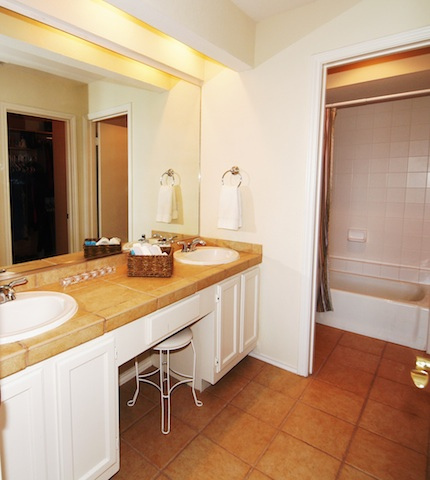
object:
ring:
[219, 163, 244, 191]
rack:
[221, 164, 242, 187]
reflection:
[343, 159, 428, 200]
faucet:
[175, 237, 206, 252]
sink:
[173, 245, 239, 266]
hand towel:
[215, 186, 243, 231]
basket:
[127, 242, 174, 277]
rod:
[324, 86, 429, 108]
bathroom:
[0, 2, 428, 478]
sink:
[0, 277, 82, 342]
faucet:
[0, 274, 30, 301]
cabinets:
[217, 271, 257, 384]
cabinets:
[61, 361, 120, 479]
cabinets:
[0, 369, 52, 477]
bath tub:
[315, 267, 429, 352]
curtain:
[315, 103, 337, 311]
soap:
[347, 229, 364, 241]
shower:
[314, 58, 428, 332]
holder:
[220, 162, 243, 187]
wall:
[201, 1, 428, 380]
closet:
[0, 108, 79, 266]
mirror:
[1, 8, 201, 281]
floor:
[112, 320, 428, 479]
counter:
[0, 236, 262, 376]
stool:
[128, 330, 206, 435]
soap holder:
[347, 227, 368, 241]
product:
[130, 242, 144, 256]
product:
[145, 246, 153, 254]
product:
[153, 242, 160, 255]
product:
[160, 249, 168, 256]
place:
[346, 226, 368, 244]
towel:
[130, 241, 167, 256]